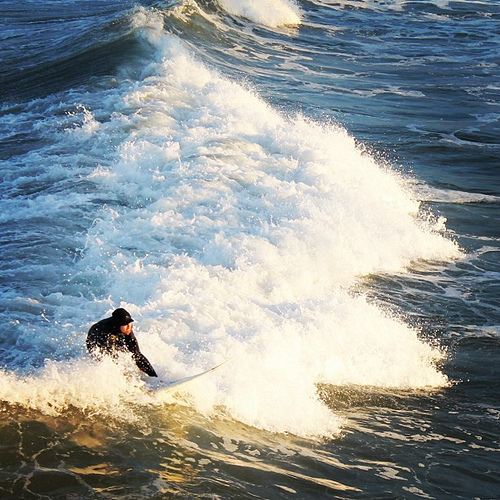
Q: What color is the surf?
A: White.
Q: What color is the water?
A: Blue.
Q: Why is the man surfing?
A: To have fun.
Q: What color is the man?
A: Black.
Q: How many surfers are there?
A: One.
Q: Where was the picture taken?
A: The beach.